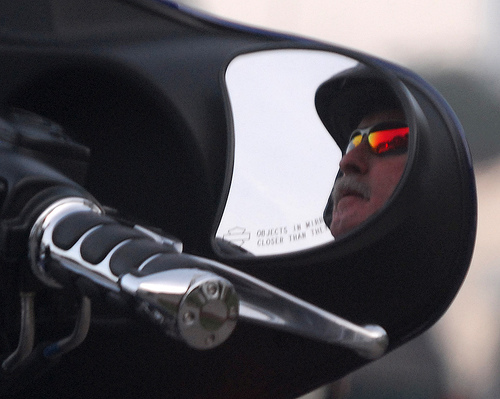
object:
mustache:
[327, 177, 371, 212]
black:
[83, 237, 105, 249]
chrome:
[143, 270, 216, 322]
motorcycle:
[0, 1, 478, 398]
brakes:
[173, 252, 389, 362]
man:
[326, 107, 414, 243]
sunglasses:
[340, 119, 412, 164]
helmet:
[311, 64, 409, 228]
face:
[329, 108, 414, 239]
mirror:
[206, 41, 432, 275]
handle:
[26, 195, 239, 352]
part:
[291, 108, 386, 186]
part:
[55, 212, 136, 278]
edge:
[209, 46, 419, 264]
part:
[247, 285, 307, 326]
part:
[243, 171, 276, 208]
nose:
[336, 141, 371, 176]